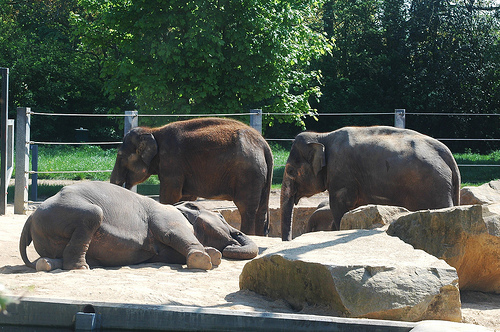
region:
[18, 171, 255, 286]
A elephant lying down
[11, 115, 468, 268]
Elephants in a zoo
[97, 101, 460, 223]
Two elephants are walking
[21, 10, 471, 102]
Trees behind the fence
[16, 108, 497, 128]
A fence with wire cable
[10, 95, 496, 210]
Fence in the zoo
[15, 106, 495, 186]
A fence behind the elephants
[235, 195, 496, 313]
Rocks inside the fence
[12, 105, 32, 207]
A concrete brick in the fence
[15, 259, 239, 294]
Sand in the ground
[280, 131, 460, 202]
this is an elephant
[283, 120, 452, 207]
the elephant is big in size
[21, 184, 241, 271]
the elephant is lying on the ground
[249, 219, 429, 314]
this is a rock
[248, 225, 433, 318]
the rock is big in size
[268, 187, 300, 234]
this is the trunk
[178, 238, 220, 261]
thee are the legs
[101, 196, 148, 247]
this is the belly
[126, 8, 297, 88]
the leaves are green in color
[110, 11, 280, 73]
the tree is leafy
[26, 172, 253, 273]
the elephant is on the ground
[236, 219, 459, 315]
the rock is huge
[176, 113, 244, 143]
hair is on the elephant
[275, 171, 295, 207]
stain is on the trunk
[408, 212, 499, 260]
the rock is huge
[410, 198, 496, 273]
the rock is grey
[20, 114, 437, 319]
the elephants are three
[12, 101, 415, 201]
the poles are four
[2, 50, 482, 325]
it is daytime in the photo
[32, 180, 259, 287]
the animal is resting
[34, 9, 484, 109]
these are some trees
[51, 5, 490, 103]
the trees are short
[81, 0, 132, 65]
the leaves are green in color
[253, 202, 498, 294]
these are some rocks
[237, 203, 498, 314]
the rocks are big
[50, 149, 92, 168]
this is the grass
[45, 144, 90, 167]
the grass is green in color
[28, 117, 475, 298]
these are some elephants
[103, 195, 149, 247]
the fur is grey in color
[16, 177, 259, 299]
this is an elephant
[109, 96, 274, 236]
this is an elephant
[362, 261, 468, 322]
this is an rock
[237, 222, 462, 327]
this is an rock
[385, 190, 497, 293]
this is an rock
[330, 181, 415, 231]
this is an rock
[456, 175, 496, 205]
this is an rock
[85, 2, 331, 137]
this is a tree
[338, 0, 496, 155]
this is a tree